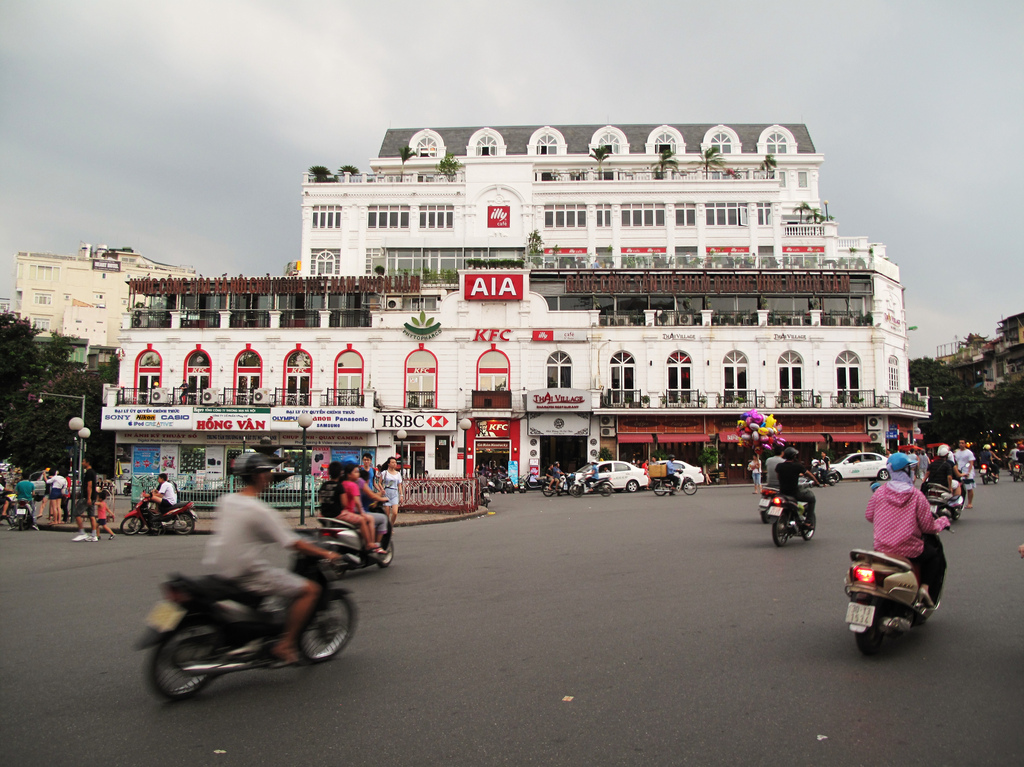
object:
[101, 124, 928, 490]
building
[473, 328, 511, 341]
kfc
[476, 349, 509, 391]
window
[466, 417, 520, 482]
doorway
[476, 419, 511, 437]
kfc sign